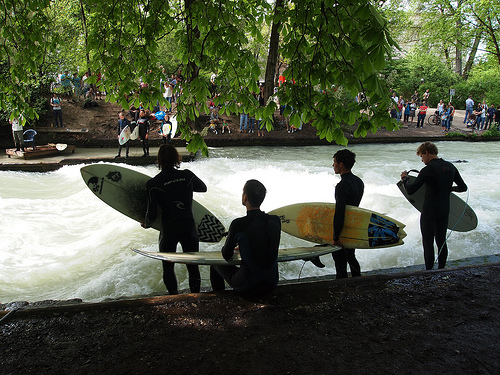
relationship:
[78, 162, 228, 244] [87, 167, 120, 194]
surfboard with designs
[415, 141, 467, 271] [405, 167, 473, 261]
man fixing strap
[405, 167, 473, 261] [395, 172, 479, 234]
strap on surfboard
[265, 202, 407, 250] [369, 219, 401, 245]
surfboard with flower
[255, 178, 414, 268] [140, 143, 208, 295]
surfboard held by man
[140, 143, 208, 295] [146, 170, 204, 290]
man wearing wetsuit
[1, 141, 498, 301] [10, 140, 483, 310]
waves on river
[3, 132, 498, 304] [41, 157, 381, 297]
river has waves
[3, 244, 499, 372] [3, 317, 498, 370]
ground full of dirt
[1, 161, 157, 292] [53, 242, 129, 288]
waves produce white foam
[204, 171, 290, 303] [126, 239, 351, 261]
man sitting with surfboard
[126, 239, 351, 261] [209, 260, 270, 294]
surfboard in h lap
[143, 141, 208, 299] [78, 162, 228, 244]
man holding surfboard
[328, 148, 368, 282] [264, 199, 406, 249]
man holding surfboard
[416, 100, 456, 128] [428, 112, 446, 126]
people block bicycle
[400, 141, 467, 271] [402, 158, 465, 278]
man wearing wetsuit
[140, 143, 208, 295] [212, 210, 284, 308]
man wearing wetsuit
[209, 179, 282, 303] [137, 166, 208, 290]
man wearing wetsuit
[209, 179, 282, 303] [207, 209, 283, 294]
man wearing wet suit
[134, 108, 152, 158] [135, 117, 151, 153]
person wearing wetsuit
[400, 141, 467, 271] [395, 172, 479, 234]
man holding surfboard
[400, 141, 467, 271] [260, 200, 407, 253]
man holding surfboard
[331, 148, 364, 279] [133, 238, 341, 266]
man holding surfboard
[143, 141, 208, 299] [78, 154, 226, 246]
man holding surf board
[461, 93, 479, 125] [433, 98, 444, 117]
person standing with person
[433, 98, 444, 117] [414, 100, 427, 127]
person standing with person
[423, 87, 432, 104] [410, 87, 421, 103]
person standing with person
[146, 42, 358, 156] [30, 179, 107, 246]
tree limbs hanging over water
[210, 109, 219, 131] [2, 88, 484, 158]
child sitting on ground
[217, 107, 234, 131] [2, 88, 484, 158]
child sitting on ground